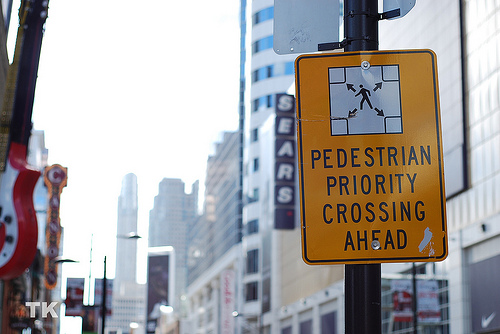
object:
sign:
[295, 49, 449, 264]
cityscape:
[0, 0, 499, 333]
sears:
[275, 94, 296, 206]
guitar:
[1, 0, 49, 282]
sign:
[0, 0, 42, 282]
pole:
[343, 1, 381, 332]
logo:
[25, 301, 60, 319]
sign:
[467, 252, 499, 333]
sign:
[44, 164, 70, 288]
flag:
[66, 276, 86, 317]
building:
[240, 2, 355, 333]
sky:
[6, 0, 243, 174]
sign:
[273, 92, 296, 230]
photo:
[0, 0, 499, 331]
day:
[1, 1, 500, 332]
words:
[311, 146, 322, 172]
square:
[329, 63, 403, 136]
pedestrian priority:
[311, 146, 431, 196]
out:
[0, 0, 50, 278]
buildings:
[112, 169, 147, 333]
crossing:
[322, 200, 426, 223]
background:
[47, 0, 497, 332]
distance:
[105, 127, 233, 334]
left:
[0, 0, 50, 280]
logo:
[478, 312, 497, 328]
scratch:
[421, 226, 438, 259]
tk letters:
[25, 301, 60, 319]